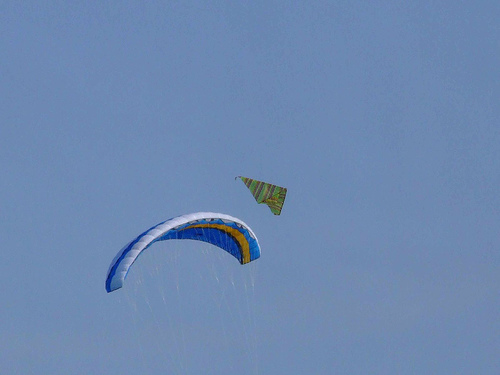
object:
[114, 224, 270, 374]
strings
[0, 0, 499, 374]
blue sky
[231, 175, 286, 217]
flying objects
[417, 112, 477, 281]
clouds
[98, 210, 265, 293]
parasail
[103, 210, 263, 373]
windsail